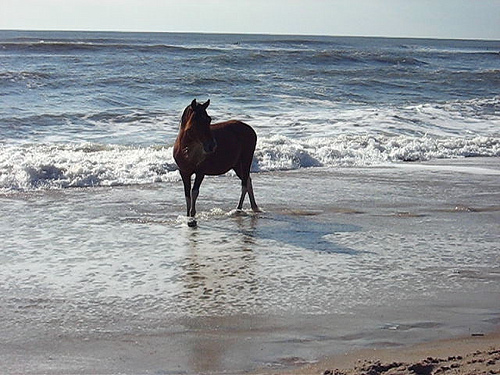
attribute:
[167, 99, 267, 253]
horse — brown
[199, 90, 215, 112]
ear — pointy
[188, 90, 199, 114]
ear — pointy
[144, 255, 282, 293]
water — shallow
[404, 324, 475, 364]
sand — wet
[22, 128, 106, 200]
seawater — foamy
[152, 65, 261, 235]
horse — brown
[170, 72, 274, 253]
horse — brown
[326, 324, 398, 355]
sand — trampled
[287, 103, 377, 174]
waves — white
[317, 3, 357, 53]
sky — pale, grey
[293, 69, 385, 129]
water — dark, blue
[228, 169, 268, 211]
leg — white